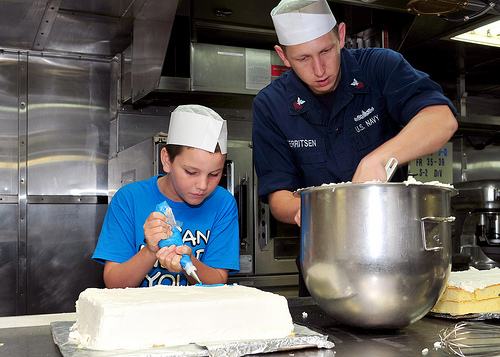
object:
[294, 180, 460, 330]
bowl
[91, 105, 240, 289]
boy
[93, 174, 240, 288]
t-shirt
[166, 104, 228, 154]
hat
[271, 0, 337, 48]
hat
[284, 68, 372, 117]
collar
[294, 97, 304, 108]
emblem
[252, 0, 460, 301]
man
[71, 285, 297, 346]
cake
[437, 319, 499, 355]
beater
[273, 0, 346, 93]
head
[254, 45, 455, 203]
uniform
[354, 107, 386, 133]
print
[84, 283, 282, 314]
frosting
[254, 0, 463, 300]
chef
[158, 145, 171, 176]
ear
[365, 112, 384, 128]
navy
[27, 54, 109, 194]
sheeting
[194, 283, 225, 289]
frosting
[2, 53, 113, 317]
wall